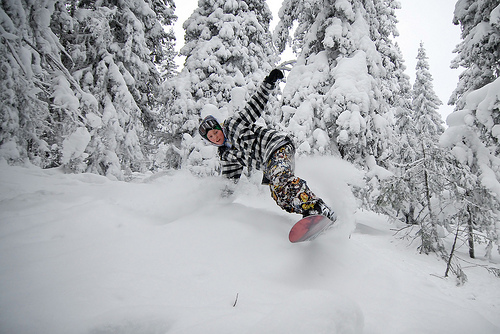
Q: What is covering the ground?
A: Snow.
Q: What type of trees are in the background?
A: Pine.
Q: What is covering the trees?
A: Snow.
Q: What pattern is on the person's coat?
A: Plaid.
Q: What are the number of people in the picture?
A: 1.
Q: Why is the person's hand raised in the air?
A: Balance.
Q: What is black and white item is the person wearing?
A: Jacket.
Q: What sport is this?
A: Snowboarding.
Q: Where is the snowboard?
A: In the air.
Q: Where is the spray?
A: In the air.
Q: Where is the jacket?
A: On the woman.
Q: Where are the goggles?
A: On the woman.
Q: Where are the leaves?
A: On the trees.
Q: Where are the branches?
A: On the tree.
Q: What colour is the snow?
A: White.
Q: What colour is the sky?
A: White.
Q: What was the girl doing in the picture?
A: Skiing.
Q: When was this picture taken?
A: Winter.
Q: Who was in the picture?
A: The girl.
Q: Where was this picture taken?
A: Mountain.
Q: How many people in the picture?
A: One.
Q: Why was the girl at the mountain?
A: Skiing.